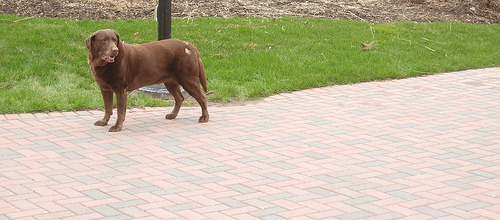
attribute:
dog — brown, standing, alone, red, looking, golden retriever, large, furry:
[84, 27, 210, 132]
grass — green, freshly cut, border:
[0, 13, 498, 115]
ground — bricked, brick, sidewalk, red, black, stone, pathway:
[1, 66, 499, 219]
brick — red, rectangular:
[240, 158, 276, 171]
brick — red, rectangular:
[372, 195, 409, 208]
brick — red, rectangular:
[468, 191, 499, 206]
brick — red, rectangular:
[184, 194, 225, 207]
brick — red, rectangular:
[115, 204, 152, 218]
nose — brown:
[112, 47, 119, 54]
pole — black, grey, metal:
[157, 1, 171, 42]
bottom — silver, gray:
[136, 82, 192, 101]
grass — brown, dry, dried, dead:
[1, 1, 498, 24]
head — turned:
[85, 29, 122, 63]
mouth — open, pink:
[101, 53, 118, 61]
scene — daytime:
[1, 1, 499, 220]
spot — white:
[181, 40, 190, 46]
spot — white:
[184, 46, 191, 55]